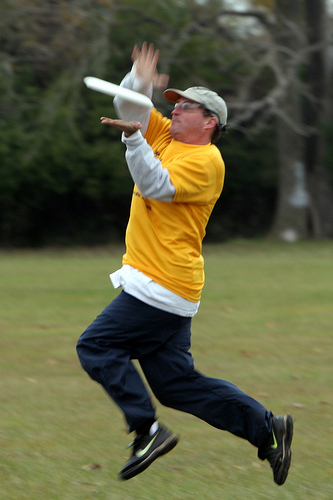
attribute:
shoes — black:
[118, 417, 286, 473]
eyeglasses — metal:
[170, 100, 206, 113]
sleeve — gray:
[111, 61, 153, 141]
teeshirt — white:
[105, 266, 200, 321]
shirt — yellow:
[131, 96, 219, 301]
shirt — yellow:
[122, 108, 224, 306]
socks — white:
[150, 420, 159, 435]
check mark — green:
[267, 432, 278, 457]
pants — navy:
[77, 293, 236, 411]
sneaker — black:
[265, 415, 292, 485]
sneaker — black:
[117, 423, 178, 481]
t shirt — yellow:
[109, 105, 224, 311]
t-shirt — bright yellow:
[137, 117, 221, 307]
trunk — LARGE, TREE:
[243, 30, 319, 257]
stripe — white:
[270, 430, 278, 449]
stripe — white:
[136, 430, 157, 457]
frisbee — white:
[82, 71, 157, 118]